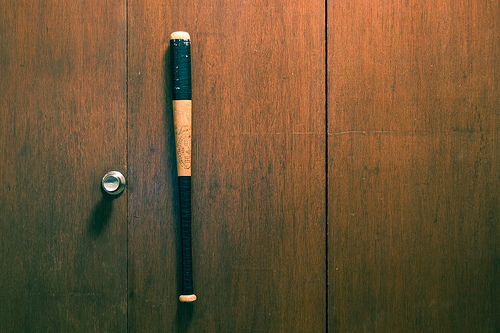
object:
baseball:
[168, 30, 198, 304]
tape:
[169, 39, 193, 101]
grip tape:
[176, 176, 192, 295]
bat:
[170, 30, 196, 301]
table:
[1, 0, 498, 328]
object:
[100, 170, 126, 195]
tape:
[176, 173, 196, 294]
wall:
[1, 0, 497, 329]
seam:
[321, 0, 330, 333]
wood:
[1, 0, 498, 333]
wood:
[170, 30, 197, 301]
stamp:
[174, 123, 194, 169]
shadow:
[86, 190, 116, 233]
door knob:
[99, 172, 127, 197]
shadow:
[177, 301, 194, 326]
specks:
[361, 7, 386, 43]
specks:
[336, 136, 388, 195]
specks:
[375, 52, 435, 89]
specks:
[270, 26, 325, 76]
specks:
[203, 12, 267, 45]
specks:
[87, 73, 120, 129]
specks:
[194, 124, 266, 192]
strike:
[352, 279, 378, 311]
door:
[323, 2, 495, 331]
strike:
[70, 149, 107, 169]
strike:
[45, 211, 89, 235]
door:
[122, 1, 323, 329]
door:
[3, 3, 322, 330]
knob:
[178, 292, 197, 303]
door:
[1, 2, 132, 331]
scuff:
[269, 128, 381, 138]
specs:
[170, 53, 183, 96]